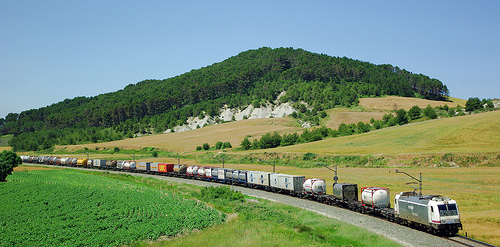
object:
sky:
[0, 0, 499, 120]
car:
[209, 169, 231, 184]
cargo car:
[268, 172, 304, 195]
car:
[357, 187, 389, 210]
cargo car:
[242, 162, 269, 189]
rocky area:
[162, 90, 313, 134]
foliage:
[0, 169, 229, 246]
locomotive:
[389, 188, 462, 234]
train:
[13, 155, 461, 239]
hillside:
[0, 81, 499, 168]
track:
[447, 230, 490, 247]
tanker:
[300, 178, 325, 196]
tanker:
[182, 166, 200, 178]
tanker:
[121, 161, 137, 172]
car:
[245, 171, 273, 187]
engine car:
[390, 189, 462, 235]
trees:
[0, 46, 450, 152]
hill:
[0, 43, 499, 169]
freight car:
[145, 162, 174, 173]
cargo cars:
[330, 180, 357, 204]